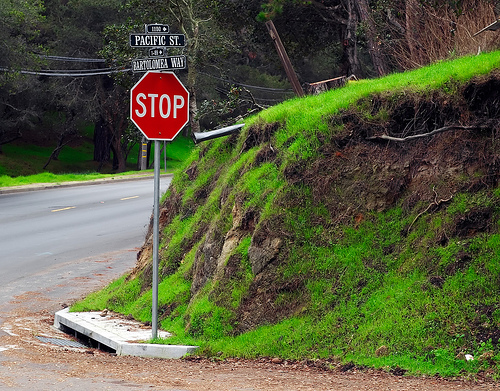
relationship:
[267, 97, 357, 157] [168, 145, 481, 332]
grass on hill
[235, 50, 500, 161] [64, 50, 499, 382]
grass growing on hill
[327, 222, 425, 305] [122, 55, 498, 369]
moss growing on a bank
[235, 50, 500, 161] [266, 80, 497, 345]
grass in a hill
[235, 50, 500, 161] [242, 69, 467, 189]
grass on hill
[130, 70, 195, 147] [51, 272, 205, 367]
stop sign on street corner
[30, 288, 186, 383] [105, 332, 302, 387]
gutter on side of road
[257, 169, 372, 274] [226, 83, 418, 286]
rocks on hill side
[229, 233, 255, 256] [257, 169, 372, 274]
moss on rocks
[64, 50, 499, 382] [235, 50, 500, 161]
hill has grass